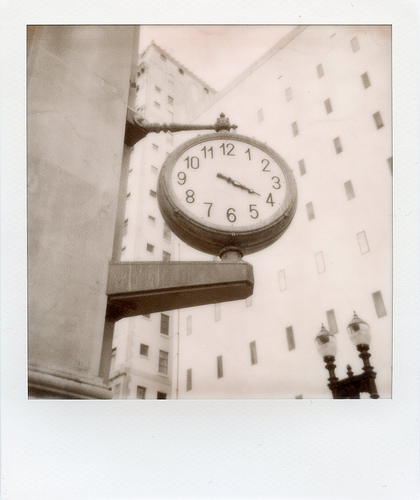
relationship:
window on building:
[362, 109, 388, 135] [164, 28, 395, 396]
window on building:
[277, 318, 298, 363] [164, 28, 395, 396]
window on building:
[207, 352, 235, 386] [164, 28, 395, 396]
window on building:
[240, 334, 261, 368] [164, 28, 395, 396]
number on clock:
[217, 138, 238, 159] [150, 124, 306, 261]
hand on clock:
[215, 171, 262, 198] [155, 129, 299, 255]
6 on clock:
[216, 195, 249, 231] [164, 134, 291, 231]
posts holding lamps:
[320, 354, 383, 393] [312, 306, 372, 357]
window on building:
[288, 112, 354, 170] [110, 28, 384, 401]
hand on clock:
[215, 169, 262, 198] [153, 133, 309, 253]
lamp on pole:
[301, 300, 382, 401] [324, 351, 344, 399]